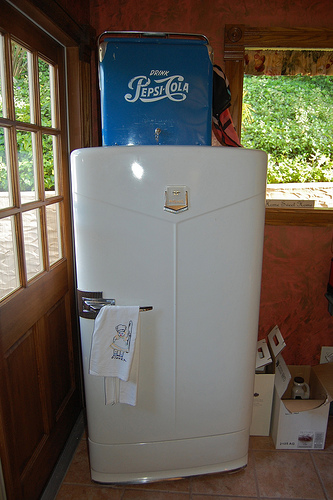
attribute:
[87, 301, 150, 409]
towel — white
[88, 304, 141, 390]
towel — white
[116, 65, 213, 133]
logo — white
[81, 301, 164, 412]
towel — white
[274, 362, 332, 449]
carton — opened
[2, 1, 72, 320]
frame — wooden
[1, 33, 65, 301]
window — framed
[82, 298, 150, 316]
handle — silver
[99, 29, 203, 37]
silver handle — long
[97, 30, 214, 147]
pepsi box — blue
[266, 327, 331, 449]
box — white, cardboard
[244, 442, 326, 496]
tile — beige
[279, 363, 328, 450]
boxes — cardboard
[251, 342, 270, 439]
boxes — cardboard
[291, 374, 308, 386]
cap — black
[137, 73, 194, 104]
pepsi cola — white, cursive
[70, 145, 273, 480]
refrigerator — white, antique, metal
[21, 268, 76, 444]
plywood — brown, wooden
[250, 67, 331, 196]
window — glass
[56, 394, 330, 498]
floor — tan, tiled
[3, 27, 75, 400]
door — brown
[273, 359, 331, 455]
box — open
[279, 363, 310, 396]
bottle — white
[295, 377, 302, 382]
lid — brown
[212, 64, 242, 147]
clothing — red, black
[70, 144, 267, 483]
fridge — old style, white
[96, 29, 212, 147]
cooler — blue